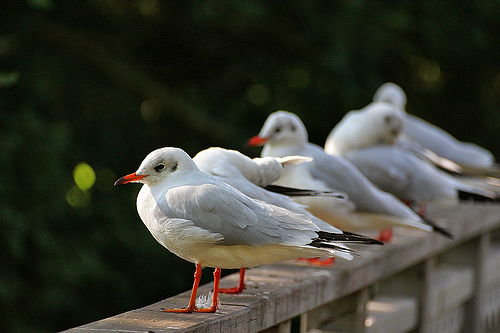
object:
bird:
[247, 103, 455, 246]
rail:
[52, 193, 499, 333]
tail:
[455, 182, 500, 207]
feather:
[196, 291, 213, 308]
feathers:
[305, 227, 382, 262]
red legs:
[238, 267, 246, 287]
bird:
[193, 145, 386, 265]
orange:
[128, 172, 142, 181]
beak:
[113, 173, 149, 186]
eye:
[153, 159, 166, 173]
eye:
[382, 113, 394, 125]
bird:
[372, 80, 499, 178]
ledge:
[85, 167, 498, 327]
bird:
[112, 146, 363, 313]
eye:
[272, 126, 282, 134]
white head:
[113, 146, 198, 188]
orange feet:
[158, 303, 196, 315]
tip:
[113, 179, 121, 187]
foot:
[193, 303, 219, 313]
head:
[365, 96, 404, 147]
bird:
[323, 101, 498, 219]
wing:
[163, 183, 322, 252]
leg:
[186, 262, 202, 309]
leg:
[210, 268, 221, 308]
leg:
[312, 253, 321, 259]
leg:
[329, 255, 337, 261]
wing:
[307, 150, 408, 220]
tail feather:
[419, 213, 456, 241]